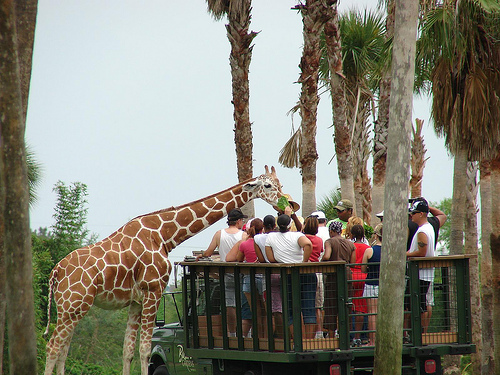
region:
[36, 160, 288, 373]
giraffe looking over back of truck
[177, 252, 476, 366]
gren raised platform on back of truck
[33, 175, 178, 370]
talll green trees and brush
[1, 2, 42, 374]
brown tree trunk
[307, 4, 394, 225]
green palm tree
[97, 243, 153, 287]
brown spots on giraffe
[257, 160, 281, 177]
two ossicones on top of giraffe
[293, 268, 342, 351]
metal grid of fence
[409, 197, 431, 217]
black and white baseball cap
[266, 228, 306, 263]
white short sleeve t-shirt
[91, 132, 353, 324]
Giraffe eating out of people's hands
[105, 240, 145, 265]
Giraffe has brown spots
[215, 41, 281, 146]
Tall palm tree behind car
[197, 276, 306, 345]
Railing surrounding the wagon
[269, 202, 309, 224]
Leaf in person's hand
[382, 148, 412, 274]
Bark missing from the trunk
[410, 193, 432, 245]
Man wearing a hat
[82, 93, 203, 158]
Sky is cloudy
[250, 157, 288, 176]
Horns on giraffe's head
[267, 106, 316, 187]
Dried palm leaf hanging down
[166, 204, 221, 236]
the giraffes neck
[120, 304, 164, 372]
the giraffes legs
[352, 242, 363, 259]
a person wearing a red shirt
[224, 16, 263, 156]
a palm tree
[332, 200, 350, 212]
a man wearing a hat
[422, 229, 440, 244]
man wearing a sleeveless white shirt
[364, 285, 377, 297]
white shorts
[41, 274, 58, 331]
the giraffes tail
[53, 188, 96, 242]
green leaves on the tree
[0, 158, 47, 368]
the tree trunk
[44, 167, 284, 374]
a giraffe in captivity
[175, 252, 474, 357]
a green painted wooden deck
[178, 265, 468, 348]
green painted fencing on deck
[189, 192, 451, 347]
a group of people on green painted deck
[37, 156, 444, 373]
people observing a giraffe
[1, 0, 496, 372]
tall limbless trees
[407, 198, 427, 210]
dark color ball cap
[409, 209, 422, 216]
a pair of black sunglasses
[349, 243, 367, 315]
an orange outfit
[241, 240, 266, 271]
a pink sleeveless shirt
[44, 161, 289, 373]
Giraffe eating out of man's hand.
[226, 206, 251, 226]
Man wearing black cap.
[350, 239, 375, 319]
Woman wearing orange dress.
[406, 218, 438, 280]
Man dressed in white sleeveless t-shirt.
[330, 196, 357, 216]
Man wearing gray cap.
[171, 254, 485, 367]
Safety cage on back of tour truck.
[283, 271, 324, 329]
Woman dressed in blue jean capris.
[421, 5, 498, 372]
Palmetto palm tree growing next to tour truck.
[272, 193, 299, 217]
Man holding leaf for giraffe.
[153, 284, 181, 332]
Rear view mirror on side of truck.